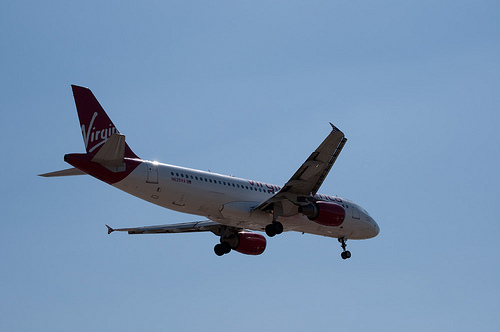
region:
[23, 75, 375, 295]
commercial jet in air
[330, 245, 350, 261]
front landing black wheels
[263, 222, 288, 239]
back set of wheels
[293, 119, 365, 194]
front side wing outstretched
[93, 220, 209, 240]
left side wing outstretched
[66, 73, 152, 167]
back tail wing with logo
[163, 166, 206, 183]
small windows on plane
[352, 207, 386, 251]
front nose of plane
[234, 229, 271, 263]
red single engine on plane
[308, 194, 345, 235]
red single engine on plane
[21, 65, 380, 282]
airplane in the sky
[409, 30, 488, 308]
blue sky in the distance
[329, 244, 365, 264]
front wheels of a plane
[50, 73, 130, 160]
tail of a plane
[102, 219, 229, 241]
left wing of a plane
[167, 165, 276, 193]
side windows of a plane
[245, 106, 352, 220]
right wing of a plane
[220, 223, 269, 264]
left engine on a plane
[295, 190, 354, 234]
right engine on a plane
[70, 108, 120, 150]
Virgin logo on plane's tail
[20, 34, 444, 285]
this is a passenger plane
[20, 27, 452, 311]
the plane is in the sky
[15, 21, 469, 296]
this is a virgin airlines plane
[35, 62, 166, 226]
the virgin airways logo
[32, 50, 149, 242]
the text is white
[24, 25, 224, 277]
the logo is red and white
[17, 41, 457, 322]
the wheels are down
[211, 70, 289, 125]
the sky is clear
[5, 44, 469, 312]
there are three wheels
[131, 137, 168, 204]
the door of the plane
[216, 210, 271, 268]
a large jet engine.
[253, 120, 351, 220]
the right wing of a jet.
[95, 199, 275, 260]
the left wing of a jet.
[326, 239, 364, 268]
landing gear on a jet.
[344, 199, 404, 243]
the cock pit of a plane.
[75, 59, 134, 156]
a tail wing of a jet.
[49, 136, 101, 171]
an engine on the back of a jet.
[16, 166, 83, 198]
a wing on a jet.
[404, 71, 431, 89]
a section of a blue sky.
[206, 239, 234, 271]
landing gear.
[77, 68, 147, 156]
a virgin logo on a wing.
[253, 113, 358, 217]
the right wing of a jetliner.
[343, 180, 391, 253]
a cock pit on a jet.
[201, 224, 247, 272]
landing gear.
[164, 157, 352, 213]
the side of an airplane.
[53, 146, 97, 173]
the rear end of a plane.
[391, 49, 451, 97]
a section of blue sky.